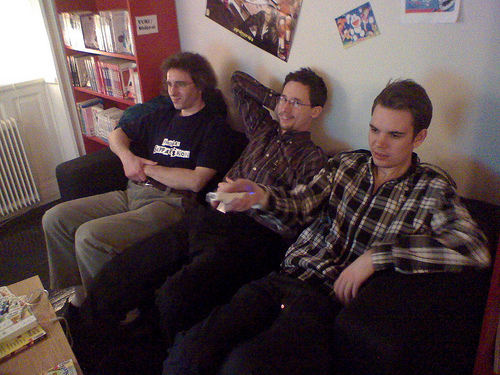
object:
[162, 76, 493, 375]
men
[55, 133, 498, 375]
couch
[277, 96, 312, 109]
eyeglasses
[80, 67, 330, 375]
man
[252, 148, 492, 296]
shirt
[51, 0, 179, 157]
bookshelf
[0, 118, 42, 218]
radiator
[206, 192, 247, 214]
remote controller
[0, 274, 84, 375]
coffee table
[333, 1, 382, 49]
cartoon drawing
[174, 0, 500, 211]
wall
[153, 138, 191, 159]
writing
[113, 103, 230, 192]
t-shirt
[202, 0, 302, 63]
poster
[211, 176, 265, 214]
hand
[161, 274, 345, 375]
pants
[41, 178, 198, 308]
pants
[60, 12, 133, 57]
books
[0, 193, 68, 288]
floor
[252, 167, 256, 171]
buttons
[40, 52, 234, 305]
guy